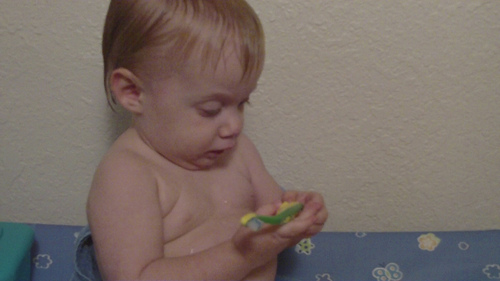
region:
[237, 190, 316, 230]
baby inspecting green and yellow toothbrush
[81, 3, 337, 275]
chubby baby with blond hair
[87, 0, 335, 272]
baby in bathroom holding toothbrush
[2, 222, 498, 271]
blue and white padded bumper around baby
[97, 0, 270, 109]
freshly wet blond hair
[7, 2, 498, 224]
white stuccato wall behind baby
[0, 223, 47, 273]
aqua guard rail behind baby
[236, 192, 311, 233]
white bristle toothbrush that is yellow on the back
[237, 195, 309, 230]
white bristles toothbrush that is green on the front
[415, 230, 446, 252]
small yellow and white flowers on padding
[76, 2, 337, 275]
A baby being bathed holding a toothbrush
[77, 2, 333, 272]
A baby being bathed holding a toothbrush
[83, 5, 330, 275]
A baby being bathed holding a toothbrush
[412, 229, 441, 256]
white design on playpen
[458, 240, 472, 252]
white design on playpen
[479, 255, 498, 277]
white design on playpen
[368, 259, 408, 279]
white design on playpen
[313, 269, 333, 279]
white design on playpen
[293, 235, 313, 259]
white design on playpen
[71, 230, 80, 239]
white design on playpen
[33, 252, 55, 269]
white design on playpen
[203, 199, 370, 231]
green and yellow toothbrush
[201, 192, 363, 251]
small hands holding brush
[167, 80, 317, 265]
baby looking down at brush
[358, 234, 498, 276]
designs on tub that baby is in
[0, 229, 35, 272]
green item in back of baby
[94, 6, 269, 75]
hair is a light blonde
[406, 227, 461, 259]
yellow flower on blue tub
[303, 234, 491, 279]
tub is blue with designs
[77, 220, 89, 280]
blue strap behind child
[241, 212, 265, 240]
brush has white bristles